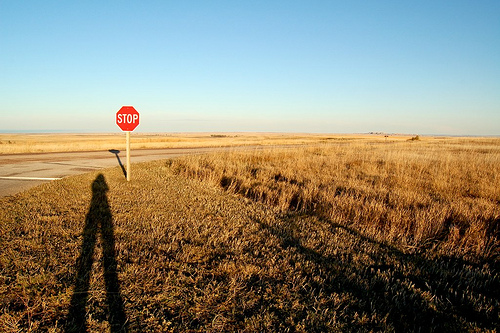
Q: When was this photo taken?
A: Daytime.